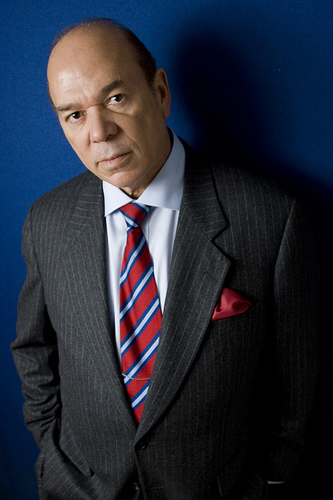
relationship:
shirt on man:
[102, 127, 186, 426] [17, 11, 262, 486]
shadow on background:
[178, 43, 265, 152] [153, 10, 322, 165]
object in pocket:
[213, 291, 254, 321] [209, 289, 262, 364]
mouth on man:
[96, 149, 135, 170] [12, 14, 322, 494]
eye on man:
[106, 88, 127, 106] [12, 14, 322, 494]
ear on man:
[153, 68, 171, 119] [12, 14, 322, 494]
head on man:
[41, 21, 159, 74] [12, 14, 322, 494]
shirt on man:
[102, 181, 183, 293] [12, 14, 322, 494]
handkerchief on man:
[212, 285, 251, 322] [12, 14, 322, 494]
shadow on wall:
[178, 43, 265, 152] [150, 3, 317, 165]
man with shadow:
[12, 14, 322, 494] [178, 43, 265, 152]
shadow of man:
[178, 43, 265, 152] [12, 14, 322, 494]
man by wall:
[12, 14, 322, 494] [169, 6, 320, 156]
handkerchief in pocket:
[213, 289, 251, 321] [208, 317, 268, 386]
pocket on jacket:
[211, 324, 269, 387] [27, 173, 321, 487]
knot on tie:
[115, 203, 158, 227] [121, 201, 166, 395]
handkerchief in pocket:
[212, 285, 248, 317] [206, 303, 253, 322]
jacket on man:
[8, 128, 331, 497] [12, 14, 322, 494]